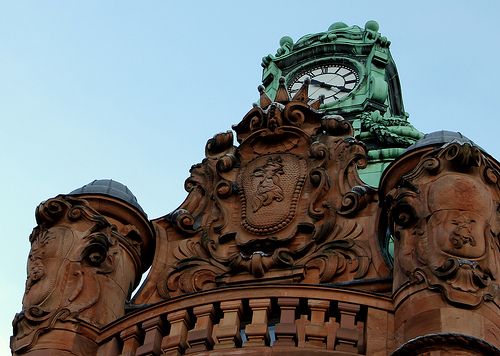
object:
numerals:
[341, 78, 359, 85]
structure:
[244, 20, 428, 194]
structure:
[377, 129, 499, 355]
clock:
[283, 55, 366, 105]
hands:
[297, 76, 324, 89]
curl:
[171, 209, 204, 237]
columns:
[154, 76, 382, 289]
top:
[241, 77, 326, 105]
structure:
[97, 281, 393, 356]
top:
[376, 128, 498, 188]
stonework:
[9, 75, 500, 356]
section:
[0, 178, 154, 355]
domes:
[58, 178, 153, 236]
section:
[378, 129, 498, 355]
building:
[250, 20, 428, 188]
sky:
[0, 0, 499, 356]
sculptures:
[10, 76, 498, 355]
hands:
[321, 78, 345, 91]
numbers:
[318, 66, 331, 73]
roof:
[69, 180, 147, 216]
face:
[287, 60, 363, 109]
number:
[329, 64, 344, 75]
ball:
[363, 19, 381, 29]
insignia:
[234, 151, 310, 238]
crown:
[249, 74, 328, 108]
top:
[64, 179, 146, 218]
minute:
[321, 82, 353, 92]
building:
[10, 74, 499, 356]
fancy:
[378, 138, 499, 311]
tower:
[7, 76, 497, 355]